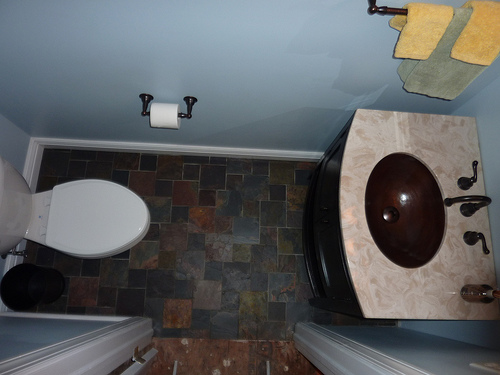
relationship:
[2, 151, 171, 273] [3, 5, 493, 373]
toilet in bathroom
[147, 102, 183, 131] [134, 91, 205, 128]
toilet paper on holder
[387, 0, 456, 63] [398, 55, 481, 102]
towel by a green towel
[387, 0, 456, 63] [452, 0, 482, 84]
towel between towel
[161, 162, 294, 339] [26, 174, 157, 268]
flooring between toilet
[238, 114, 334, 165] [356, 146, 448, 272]
ground between sink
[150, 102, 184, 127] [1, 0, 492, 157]
toilet paper on wall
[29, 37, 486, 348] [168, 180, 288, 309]
bathroom has floor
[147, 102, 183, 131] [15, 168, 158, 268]
toilet paper near toilet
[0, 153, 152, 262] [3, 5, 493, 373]
toilet bowl in bathroom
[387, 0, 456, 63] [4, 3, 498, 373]
towel in restroom